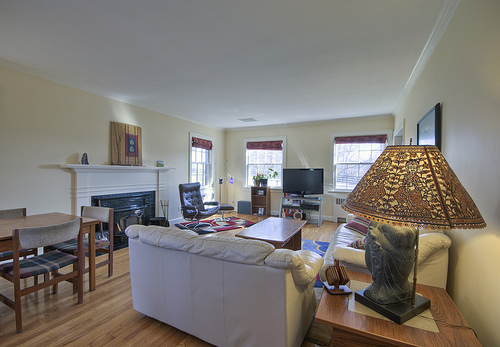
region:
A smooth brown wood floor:
[110, 310, 165, 343]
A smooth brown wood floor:
[26, 305, 99, 345]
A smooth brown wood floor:
[85, 271, 135, 325]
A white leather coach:
[121, 218, 363, 340]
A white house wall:
[448, 65, 498, 167]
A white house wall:
[282, 125, 324, 162]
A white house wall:
[144, 118, 185, 168]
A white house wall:
[28, 70, 89, 148]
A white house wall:
[4, 80, 62, 212]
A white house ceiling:
[150, 14, 415, 106]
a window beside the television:
[242, 137, 325, 206]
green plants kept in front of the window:
[243, 136, 285, 193]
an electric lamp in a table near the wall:
[314, 126, 497, 343]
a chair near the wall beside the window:
[176, 122, 222, 230]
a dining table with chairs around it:
[0, 202, 116, 327]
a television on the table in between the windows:
[240, 134, 394, 223]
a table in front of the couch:
[126, 212, 322, 345]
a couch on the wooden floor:
[116, 223, 322, 342]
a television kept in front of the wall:
[276, 148, 333, 204]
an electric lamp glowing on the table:
[315, 145, 486, 343]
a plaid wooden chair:
[1, 215, 84, 329]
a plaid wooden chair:
[42, 202, 116, 289]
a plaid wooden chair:
[0, 207, 42, 293]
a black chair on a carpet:
[179, 180, 221, 231]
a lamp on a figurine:
[347, 139, 487, 334]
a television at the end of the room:
[279, 167, 325, 197]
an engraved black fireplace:
[88, 189, 165, 249]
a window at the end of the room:
[243, 138, 290, 190]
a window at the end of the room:
[188, 128, 215, 192]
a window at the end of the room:
[329, 132, 393, 193]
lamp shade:
[367, 155, 441, 216]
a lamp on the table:
[349, 143, 481, 317]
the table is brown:
[323, 298, 343, 320]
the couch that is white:
[126, 222, 301, 341]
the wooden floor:
[56, 302, 111, 345]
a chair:
[10, 228, 83, 313]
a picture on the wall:
[106, 124, 148, 163]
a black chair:
[174, 180, 219, 216]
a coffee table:
[255, 214, 294, 238]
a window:
[249, 149, 281, 173]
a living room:
[2, 91, 462, 317]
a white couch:
[130, 221, 308, 343]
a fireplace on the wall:
[69, 155, 169, 229]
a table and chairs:
[11, 189, 115, 284]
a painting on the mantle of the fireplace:
[108, 125, 139, 153]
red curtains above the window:
[189, 135, 223, 147]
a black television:
[268, 156, 322, 191]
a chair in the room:
[172, 184, 234, 219]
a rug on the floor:
[188, 210, 255, 230]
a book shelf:
[253, 186, 273, 214]